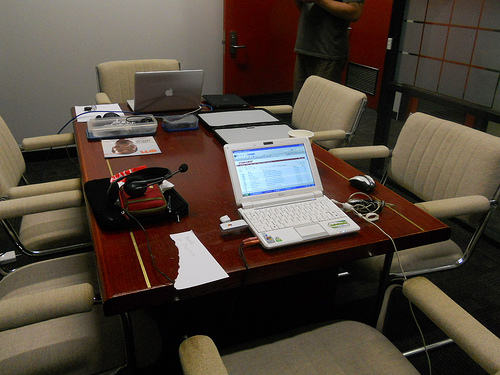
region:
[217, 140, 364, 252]
white laptop on desk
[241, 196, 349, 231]
white keys of a keyboard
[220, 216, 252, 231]
white usb stick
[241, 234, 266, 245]
two red cords plug into a laptop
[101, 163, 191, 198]
black earphones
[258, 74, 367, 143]
tan seat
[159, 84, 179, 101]
apple logo on silver laptop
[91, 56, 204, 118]
Apple laptop in front of tan seat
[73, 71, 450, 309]
brown table covered with paper and electronic devices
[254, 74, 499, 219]
two tan seats under a brown table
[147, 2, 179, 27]
part of a wall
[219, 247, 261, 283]
edge of a table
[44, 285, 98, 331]
part of a handle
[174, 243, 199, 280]
part of a paper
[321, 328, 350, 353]
part of a chair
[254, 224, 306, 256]
edge of a laptop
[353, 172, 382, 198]
part of a mouse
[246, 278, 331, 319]
part of a table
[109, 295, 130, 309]
edge of a table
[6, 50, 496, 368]
Beige and silver chairs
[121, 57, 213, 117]
A silver laptop with a white apple logo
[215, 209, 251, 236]
White USB plugged into the laptop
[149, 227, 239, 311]
Torn piece of white paper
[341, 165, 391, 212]
Black and white mouse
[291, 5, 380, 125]
Person wearing a brown shirt and pants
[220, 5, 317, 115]
Red door with a silver handle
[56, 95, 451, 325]
Rectangular brown desk in middle of room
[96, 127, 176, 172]
White magazine cover with the image of a person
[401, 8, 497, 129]
Etched glass in the window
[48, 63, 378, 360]
brown desk with office equipment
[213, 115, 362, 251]
white laptop open on desk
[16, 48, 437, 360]
six brown chairs around desk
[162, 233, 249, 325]
white piece of paper ripped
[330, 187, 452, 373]
power cord plugged into white laptop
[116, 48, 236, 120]
silver laptop on desk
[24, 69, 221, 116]
silver laptop with power cord plugged in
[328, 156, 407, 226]
black and white mouse on desk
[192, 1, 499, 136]
brown office door open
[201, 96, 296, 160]
closed laptop on desk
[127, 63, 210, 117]
a silver laptop on a table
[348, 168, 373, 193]
a silver mouse on a table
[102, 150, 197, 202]
a black headset on a table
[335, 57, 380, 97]
a metal vent in the wall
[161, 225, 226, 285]
a ripped piece of paper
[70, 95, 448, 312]
a brown wood table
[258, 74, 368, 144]
a tan padded chair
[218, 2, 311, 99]
an open red door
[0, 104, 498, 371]
a gray carpeted floor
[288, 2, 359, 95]
a man in a grey shirt